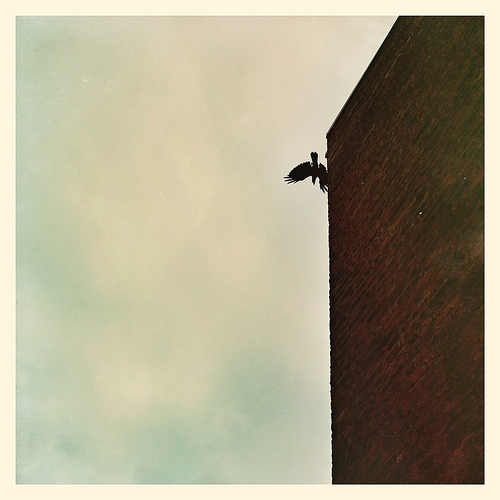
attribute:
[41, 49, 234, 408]
clouds — misty, grey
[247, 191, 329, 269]
sillhouette — head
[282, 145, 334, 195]
bird — in the sky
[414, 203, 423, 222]
spot — white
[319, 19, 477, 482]
building — brown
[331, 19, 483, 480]
building — tall, windowless, red, brick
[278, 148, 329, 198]
bird — medium sized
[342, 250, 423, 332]
brick — red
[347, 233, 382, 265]
brick — red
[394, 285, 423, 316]
brick — red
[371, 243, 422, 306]
brick — red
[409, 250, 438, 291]
brick — red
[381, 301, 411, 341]
brick — red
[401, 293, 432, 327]
brick — red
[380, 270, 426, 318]
brick — red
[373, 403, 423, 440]
brick — red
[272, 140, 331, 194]
bird — sillhouete of bird